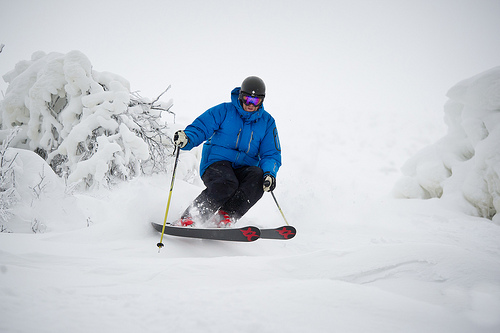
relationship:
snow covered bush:
[0, 0, 499, 333] [1, 41, 184, 234]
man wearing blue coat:
[140, 57, 351, 237] [174, 98, 286, 172]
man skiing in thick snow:
[170, 74, 289, 237] [377, 240, 464, 309]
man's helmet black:
[143, 68, 382, 262] [242, 79, 263, 96]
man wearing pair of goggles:
[170, 74, 289, 237] [235, 88, 266, 104]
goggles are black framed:
[242, 88, 267, 109] [239, 95, 264, 105]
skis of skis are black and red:
[148, 220, 303, 250] [240, 227, 263, 239]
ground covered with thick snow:
[18, 191, 486, 330] [275, 286, 344, 326]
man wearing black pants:
[170, 74, 289, 237] [199, 163, 269, 234]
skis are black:
[148, 220, 303, 250] [209, 230, 234, 240]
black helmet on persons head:
[235, 76, 272, 98] [235, 65, 273, 117]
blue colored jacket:
[221, 125, 245, 149] [175, 107, 294, 177]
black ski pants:
[231, 172, 244, 192] [197, 152, 270, 225]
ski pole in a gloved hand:
[145, 141, 183, 255] [164, 107, 236, 145]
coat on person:
[182, 85, 284, 180] [157, 75, 292, 242]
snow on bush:
[0, 0, 499, 333] [1, 41, 184, 234]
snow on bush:
[391, 62, 499, 225] [393, 68, 496, 226]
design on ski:
[240, 224, 259, 237] [148, 221, 264, 241]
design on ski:
[276, 221, 294, 239] [254, 224, 296, 239]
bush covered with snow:
[1, 41, 184, 234] [0, 0, 499, 333]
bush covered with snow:
[393, 68, 496, 226] [391, 62, 499, 225]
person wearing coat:
[157, 75, 292, 242] [174, 98, 286, 172]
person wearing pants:
[157, 75, 292, 242] [192, 158, 264, 218]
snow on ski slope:
[0, 0, 499, 333] [0, 161, 499, 330]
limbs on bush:
[44, 81, 180, 184] [1, 41, 184, 234]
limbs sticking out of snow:
[44, 81, 180, 184] [0, 0, 499, 333]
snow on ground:
[0, 0, 499, 333] [0, 163, 500, 329]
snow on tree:
[0, 0, 499, 333] [0, 44, 185, 195]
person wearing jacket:
[157, 75, 292, 242] [182, 81, 284, 180]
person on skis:
[157, 75, 292, 242] [148, 220, 299, 242]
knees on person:
[208, 164, 269, 201] [157, 75, 292, 242]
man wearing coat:
[170, 74, 289, 237] [174, 98, 286, 172]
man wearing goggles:
[170, 74, 289, 237] [242, 89, 263, 106]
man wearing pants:
[170, 74, 289, 237] [197, 160, 270, 220]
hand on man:
[171, 130, 191, 145] [159, 67, 284, 227]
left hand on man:
[258, 170, 279, 200] [170, 69, 298, 232]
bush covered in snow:
[1, 41, 184, 234] [7, 36, 492, 320]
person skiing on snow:
[157, 75, 292, 242] [7, 36, 492, 320]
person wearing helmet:
[157, 75, 292, 242] [227, 74, 268, 123]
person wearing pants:
[153, 60, 295, 242] [187, 154, 268, 246]